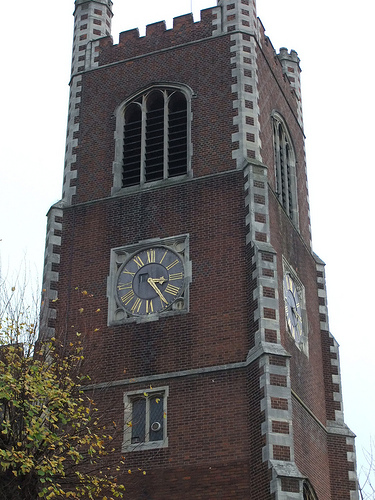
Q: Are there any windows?
A: Yes, there is a window.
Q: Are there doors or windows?
A: Yes, there is a window.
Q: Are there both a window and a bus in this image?
A: No, there is a window but no buses.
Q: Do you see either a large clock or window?
A: Yes, there is a large window.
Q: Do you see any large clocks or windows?
A: Yes, there is a large window.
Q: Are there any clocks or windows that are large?
A: Yes, the window is large.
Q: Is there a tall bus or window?
A: Yes, there is a tall window.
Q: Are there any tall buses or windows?
A: Yes, there is a tall window.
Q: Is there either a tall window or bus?
A: Yes, there is a tall window.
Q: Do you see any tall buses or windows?
A: Yes, there is a tall window.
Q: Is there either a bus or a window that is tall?
A: Yes, the window is tall.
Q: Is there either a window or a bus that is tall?
A: Yes, the window is tall.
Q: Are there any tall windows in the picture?
A: Yes, there is a tall window.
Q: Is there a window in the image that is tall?
A: Yes, there is a window that is tall.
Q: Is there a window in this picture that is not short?
A: Yes, there is a tall window.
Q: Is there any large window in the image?
A: Yes, there is a large window.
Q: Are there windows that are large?
A: Yes, there is a window that is large.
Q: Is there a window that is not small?
A: Yes, there is a large window.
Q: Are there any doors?
A: No, there are no doors.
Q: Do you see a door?
A: No, there are no doors.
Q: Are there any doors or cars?
A: No, there are no doors or cars.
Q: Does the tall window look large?
A: Yes, the window is large.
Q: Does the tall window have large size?
A: Yes, the window is large.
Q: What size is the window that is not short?
A: The window is large.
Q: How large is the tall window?
A: The window is large.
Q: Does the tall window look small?
A: No, the window is large.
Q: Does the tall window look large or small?
A: The window is large.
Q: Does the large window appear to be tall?
A: Yes, the window is tall.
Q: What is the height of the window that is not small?
A: The window is tall.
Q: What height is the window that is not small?
A: The window is tall.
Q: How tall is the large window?
A: The window is tall.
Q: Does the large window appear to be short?
A: No, the window is tall.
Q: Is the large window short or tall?
A: The window is tall.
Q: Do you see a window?
A: Yes, there is a window.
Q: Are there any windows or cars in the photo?
A: Yes, there is a window.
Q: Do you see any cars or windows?
A: Yes, there is a window.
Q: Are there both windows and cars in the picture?
A: No, there is a window but no cars.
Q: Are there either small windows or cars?
A: Yes, there is a small window.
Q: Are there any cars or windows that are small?
A: Yes, the window is small.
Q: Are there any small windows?
A: Yes, there is a small window.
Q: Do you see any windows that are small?
A: Yes, there is a window that is small.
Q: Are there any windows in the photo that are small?
A: Yes, there is a window that is small.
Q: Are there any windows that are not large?
A: Yes, there is a small window.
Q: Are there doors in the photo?
A: No, there are no doors.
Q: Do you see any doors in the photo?
A: No, there are no doors.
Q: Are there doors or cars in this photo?
A: No, there are no doors or cars.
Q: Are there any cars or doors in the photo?
A: No, there are no doors or cars.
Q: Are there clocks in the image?
A: Yes, there is a clock.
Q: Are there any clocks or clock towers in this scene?
A: Yes, there is a clock.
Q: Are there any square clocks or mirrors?
A: Yes, there is a square clock.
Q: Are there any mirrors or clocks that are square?
A: Yes, the clock is square.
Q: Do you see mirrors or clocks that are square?
A: Yes, the clock is square.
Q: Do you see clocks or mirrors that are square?
A: Yes, the clock is square.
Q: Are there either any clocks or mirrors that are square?
A: Yes, the clock is square.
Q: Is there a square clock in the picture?
A: Yes, there is a square clock.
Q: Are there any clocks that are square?
A: Yes, there is a clock that is square.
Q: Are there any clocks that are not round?
A: Yes, there is a square clock.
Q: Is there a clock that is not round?
A: Yes, there is a square clock.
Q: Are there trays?
A: No, there are no trays.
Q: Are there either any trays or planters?
A: No, there are no trays or planters.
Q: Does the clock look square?
A: Yes, the clock is square.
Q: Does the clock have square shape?
A: Yes, the clock is square.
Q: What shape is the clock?
A: The clock is square.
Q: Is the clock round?
A: No, the clock is square.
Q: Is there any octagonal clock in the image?
A: No, there is a clock but it is square.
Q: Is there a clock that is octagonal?
A: No, there is a clock but it is square.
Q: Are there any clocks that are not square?
A: No, there is a clock but it is square.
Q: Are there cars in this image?
A: No, there are no cars.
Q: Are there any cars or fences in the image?
A: No, there are no cars or fences.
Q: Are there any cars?
A: No, there are no cars.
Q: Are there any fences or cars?
A: No, there are no cars or fences.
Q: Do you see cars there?
A: No, there are no cars.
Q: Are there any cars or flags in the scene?
A: No, there are no cars or flags.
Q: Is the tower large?
A: Yes, the tower is large.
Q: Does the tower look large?
A: Yes, the tower is large.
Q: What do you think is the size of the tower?
A: The tower is large.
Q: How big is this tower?
A: The tower is large.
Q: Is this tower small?
A: No, the tower is large.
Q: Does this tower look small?
A: No, the tower is large.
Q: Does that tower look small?
A: No, the tower is large.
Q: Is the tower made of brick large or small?
A: The tower is large.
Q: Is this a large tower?
A: Yes, this is a large tower.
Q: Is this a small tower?
A: No, this is a large tower.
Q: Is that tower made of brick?
A: Yes, the tower is made of brick.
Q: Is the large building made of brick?
A: Yes, the tower is made of brick.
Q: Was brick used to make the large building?
A: Yes, the tower is made of brick.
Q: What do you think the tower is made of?
A: The tower is made of brick.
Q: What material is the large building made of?
A: The tower is made of brick.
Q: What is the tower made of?
A: The tower is made of brick.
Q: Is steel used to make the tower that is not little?
A: No, the tower is made of brick.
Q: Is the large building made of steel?
A: No, the tower is made of brick.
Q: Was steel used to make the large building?
A: No, the tower is made of brick.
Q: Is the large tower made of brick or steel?
A: The tower is made of brick.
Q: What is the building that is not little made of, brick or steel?
A: The tower is made of brick.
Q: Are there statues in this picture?
A: No, there are no statues.